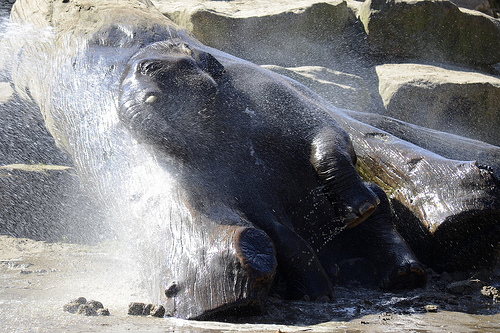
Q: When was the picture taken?
A: During the day.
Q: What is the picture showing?
A: A rock statue.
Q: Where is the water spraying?
A: On the statue.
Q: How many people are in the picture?
A: None.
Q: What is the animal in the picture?
A: An elephant.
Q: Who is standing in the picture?
A: No one.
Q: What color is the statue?
A: Brown.